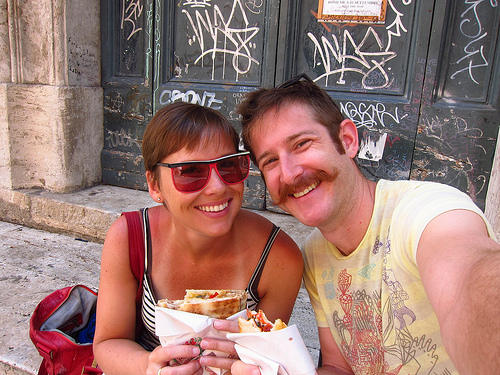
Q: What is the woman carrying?
A: A red bag.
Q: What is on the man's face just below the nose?
A: A moustache.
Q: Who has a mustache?
A: The man.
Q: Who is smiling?
A: Woman and man.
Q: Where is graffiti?
A: On the building.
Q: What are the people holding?
A: Sandwiches.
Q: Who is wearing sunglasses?
A: The woman.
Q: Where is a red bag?
A: Next to the woman.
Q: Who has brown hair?
A: Both the man and woman.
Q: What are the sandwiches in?
A: White napkins.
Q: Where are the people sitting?
A: On a step.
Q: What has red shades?
A: The sunglasses.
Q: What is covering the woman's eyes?
A: Sunglasses.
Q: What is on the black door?
A: Graffiti.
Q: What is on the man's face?
A: A moustache.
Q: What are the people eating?
A: Paninis.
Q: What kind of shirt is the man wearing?
A: A yellow t-shirt.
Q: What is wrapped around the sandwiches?
A: Paper.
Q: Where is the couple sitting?
A: On a step.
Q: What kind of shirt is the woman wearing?
A: A striped tank top.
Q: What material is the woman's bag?
A: Leather.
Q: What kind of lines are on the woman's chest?
A: Tan lines.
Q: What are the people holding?
A: Sandwiches.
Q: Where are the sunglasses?
A: On the woman's face.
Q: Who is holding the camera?
A: Man.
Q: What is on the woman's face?
A: Sunglasses.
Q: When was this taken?
A: Daytime.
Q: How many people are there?
A: 2.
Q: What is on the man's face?
A: Mustache.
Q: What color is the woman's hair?
A: Brown.